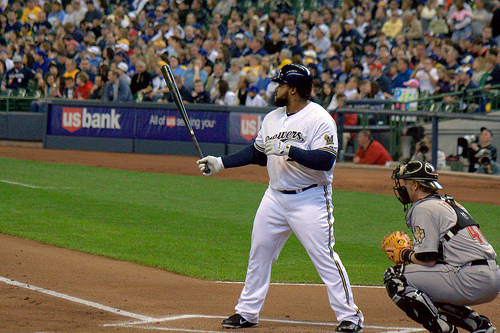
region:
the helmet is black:
[258, 41, 328, 113]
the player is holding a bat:
[142, 50, 238, 205]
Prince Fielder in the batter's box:
[161, 63, 363, 332]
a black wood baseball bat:
[159, 60, 210, 172]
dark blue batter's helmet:
[272, 63, 309, 98]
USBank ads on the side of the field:
[50, 103, 269, 158]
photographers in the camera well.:
[400, 117, 497, 174]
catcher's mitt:
[384, 231, 411, 265]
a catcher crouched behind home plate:
[382, 162, 498, 331]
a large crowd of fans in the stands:
[0, 1, 489, 105]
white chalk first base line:
[0, 275, 156, 322]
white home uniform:
[224, 102, 364, 324]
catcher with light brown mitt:
[379, 227, 414, 264]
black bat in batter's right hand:
[153, 57, 228, 177]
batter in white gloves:
[191, 135, 295, 177]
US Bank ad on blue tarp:
[53, 99, 266, 154]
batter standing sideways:
[193, 56, 373, 328]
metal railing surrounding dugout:
[332, 73, 498, 176]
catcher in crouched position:
[376, 150, 498, 330]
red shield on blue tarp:
[58, 108, 83, 134]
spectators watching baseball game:
[0, 0, 499, 119]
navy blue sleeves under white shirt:
[216, 140, 338, 172]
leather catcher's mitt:
[371, 223, 415, 268]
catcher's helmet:
[381, 152, 447, 207]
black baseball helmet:
[261, 58, 323, 106]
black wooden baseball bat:
[149, 60, 216, 177]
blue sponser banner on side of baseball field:
[49, 105, 263, 142]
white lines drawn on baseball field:
[1, 263, 429, 332]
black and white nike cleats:
[217, 301, 367, 331]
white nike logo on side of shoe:
[237, 312, 253, 326]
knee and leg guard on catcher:
[381, 260, 497, 331]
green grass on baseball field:
[2, 148, 499, 293]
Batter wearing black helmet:
[197, 62, 364, 330]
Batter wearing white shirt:
[251, 103, 339, 191]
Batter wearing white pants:
[197, 61, 367, 331]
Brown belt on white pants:
[275, 181, 318, 200]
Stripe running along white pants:
[322, 180, 361, 318]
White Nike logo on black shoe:
[236, 316, 251, 324]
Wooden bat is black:
[158, 64, 210, 174]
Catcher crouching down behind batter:
[378, 160, 498, 332]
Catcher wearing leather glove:
[377, 158, 499, 330]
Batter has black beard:
[190, 63, 364, 331]